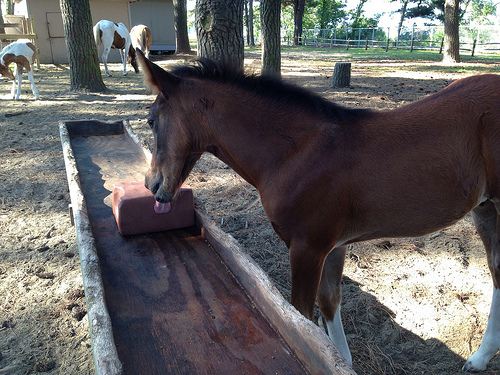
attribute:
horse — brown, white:
[119, 56, 499, 360]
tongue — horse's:
[152, 194, 176, 212]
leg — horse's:
[327, 246, 357, 373]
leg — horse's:
[286, 252, 321, 354]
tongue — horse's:
[153, 199, 172, 212]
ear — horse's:
[135, 50, 174, 94]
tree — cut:
[330, 58, 360, 96]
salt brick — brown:
[112, 175, 200, 236]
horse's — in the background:
[0, 6, 158, 106]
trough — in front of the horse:
[56, 112, 326, 371]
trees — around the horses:
[47, 0, 468, 115]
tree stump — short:
[330, 57, 354, 91]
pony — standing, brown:
[130, 43, 482, 358]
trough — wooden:
[56, 111, 350, 361]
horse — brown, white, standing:
[4, 37, 41, 105]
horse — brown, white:
[79, 4, 145, 71]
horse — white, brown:
[137, 29, 178, 59]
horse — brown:
[193, 38, 463, 327]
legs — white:
[321, 264, 497, 373]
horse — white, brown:
[91, 14, 152, 67]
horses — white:
[5, 31, 158, 88]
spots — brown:
[10, 37, 27, 79]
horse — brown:
[130, 54, 419, 294]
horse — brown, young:
[147, 49, 467, 349]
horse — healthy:
[158, 71, 378, 256]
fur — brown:
[240, 124, 355, 202]